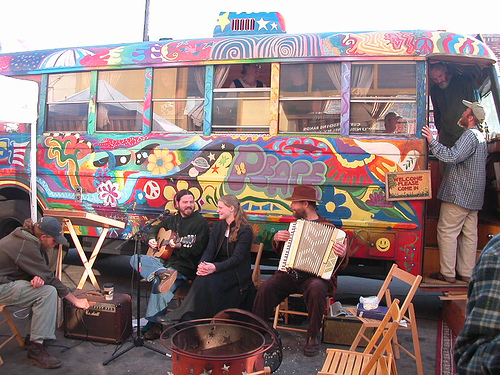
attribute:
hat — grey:
[38, 215, 70, 245]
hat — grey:
[460, 98, 485, 121]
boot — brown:
[427, 250, 479, 283]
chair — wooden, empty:
[317, 299, 400, 367]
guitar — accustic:
[138, 221, 201, 261]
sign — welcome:
[385, 169, 430, 201]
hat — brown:
[456, 93, 493, 122]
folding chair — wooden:
[315, 299, 403, 374]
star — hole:
[219, 362, 231, 372]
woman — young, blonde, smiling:
[179, 197, 258, 312]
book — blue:
[352, 294, 391, 331]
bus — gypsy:
[4, 50, 498, 278]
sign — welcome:
[386, 174, 431, 199]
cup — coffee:
[95, 277, 135, 317]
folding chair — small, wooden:
[324, 299, 405, 373]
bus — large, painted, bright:
[0, 7, 498, 279]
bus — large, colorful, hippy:
[1, 6, 496, 252]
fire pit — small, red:
[153, 305, 292, 373]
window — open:
[201, 60, 273, 139]